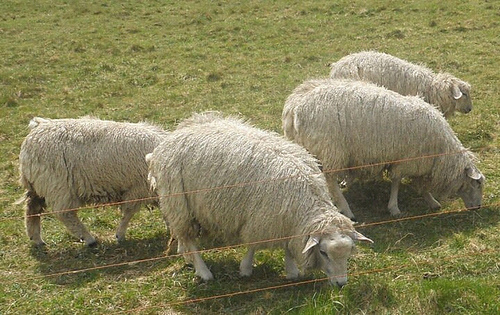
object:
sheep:
[18, 117, 172, 250]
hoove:
[84, 237, 101, 249]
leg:
[48, 196, 100, 246]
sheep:
[324, 48, 474, 119]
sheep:
[145, 110, 375, 288]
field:
[0, 0, 499, 314]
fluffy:
[18, 111, 167, 205]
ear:
[342, 227, 374, 243]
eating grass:
[94, 63, 498, 309]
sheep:
[281, 92, 491, 228]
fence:
[3, 157, 482, 311]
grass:
[4, 2, 500, 315]